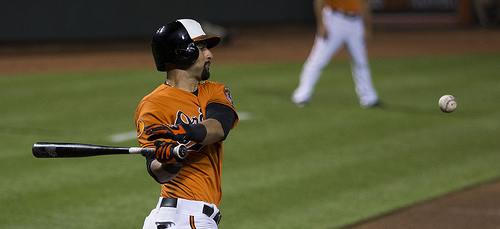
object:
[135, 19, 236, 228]
man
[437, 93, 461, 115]
ball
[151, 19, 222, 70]
helmet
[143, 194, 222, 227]
pants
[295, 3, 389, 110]
man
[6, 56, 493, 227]
grass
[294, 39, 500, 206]
air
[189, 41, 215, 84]
face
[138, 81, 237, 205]
shirt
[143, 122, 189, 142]
gloves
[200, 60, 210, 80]
beard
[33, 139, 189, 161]
bat